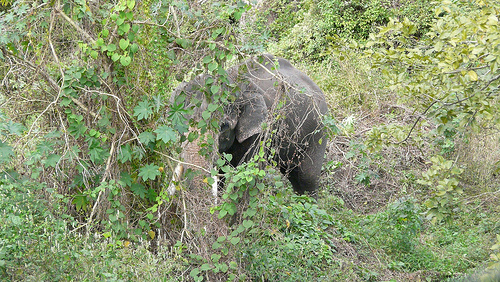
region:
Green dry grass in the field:
[357, 99, 411, 190]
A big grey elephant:
[195, 54, 379, 181]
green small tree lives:
[110, 139, 161, 183]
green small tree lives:
[171, 239, 242, 280]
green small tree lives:
[217, 147, 249, 192]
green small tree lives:
[132, 83, 180, 120]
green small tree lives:
[94, 17, 132, 64]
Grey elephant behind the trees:
[174, 53, 329, 193]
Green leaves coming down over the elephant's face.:
[162, 4, 248, 134]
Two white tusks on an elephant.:
[168, 162, 221, 207]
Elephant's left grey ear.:
[238, 89, 271, 142]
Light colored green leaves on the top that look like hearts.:
[73, 0, 138, 68]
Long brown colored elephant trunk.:
[176, 125, 216, 237]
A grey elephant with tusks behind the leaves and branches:
[170, 50, 330, 209]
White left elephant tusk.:
[208, 165, 218, 210]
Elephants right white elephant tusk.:
[167, 156, 182, 196]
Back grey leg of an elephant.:
[298, 134, 328, 189]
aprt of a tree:
[202, 151, 217, 176]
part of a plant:
[371, 213, 386, 251]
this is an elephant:
[171, 38, 366, 205]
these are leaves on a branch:
[134, 92, 171, 159]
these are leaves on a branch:
[215, 193, 262, 245]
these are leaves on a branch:
[101, 126, 172, 197]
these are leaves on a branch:
[31, 129, 76, 171]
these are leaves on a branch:
[405, 55, 444, 107]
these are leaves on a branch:
[93, 30, 136, 72]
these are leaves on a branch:
[111, 86, 176, 158]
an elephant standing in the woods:
[216, 42, 343, 211]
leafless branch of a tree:
[87, 94, 208, 209]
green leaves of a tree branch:
[391, 9, 492, 117]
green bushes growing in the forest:
[293, 7, 414, 66]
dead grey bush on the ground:
[349, 97, 427, 215]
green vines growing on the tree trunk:
[129, 32, 175, 225]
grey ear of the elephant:
[238, 89, 265, 146]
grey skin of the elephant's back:
[284, 62, 312, 91]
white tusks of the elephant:
[161, 157, 224, 215]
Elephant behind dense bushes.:
[163, 52, 320, 224]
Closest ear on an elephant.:
[235, 88, 270, 143]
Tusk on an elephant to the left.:
[155, 159, 178, 214]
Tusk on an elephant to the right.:
[207, 152, 225, 220]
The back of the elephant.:
[168, 41, 355, 202]